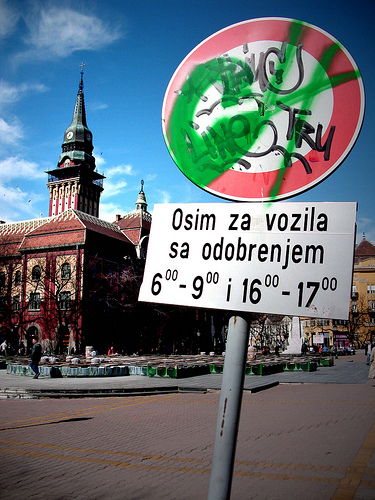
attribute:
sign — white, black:
[137, 200, 359, 322]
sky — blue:
[106, 70, 146, 126]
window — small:
[40, 306, 83, 362]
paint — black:
[279, 105, 331, 147]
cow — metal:
[200, 316, 249, 481]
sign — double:
[140, 18, 364, 321]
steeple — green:
[59, 57, 94, 145]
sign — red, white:
[131, 8, 362, 203]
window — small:
[26, 261, 44, 281]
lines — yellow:
[1, 388, 179, 427]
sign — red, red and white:
[161, 16, 365, 202]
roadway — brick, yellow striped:
[8, 382, 369, 499]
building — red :
[0, 53, 219, 365]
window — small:
[365, 282, 373, 294]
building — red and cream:
[2, 61, 149, 353]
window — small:
[52, 288, 73, 312]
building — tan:
[351, 235, 374, 348]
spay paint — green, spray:
[149, 23, 359, 178]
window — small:
[61, 261, 69, 278]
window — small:
[56, 291, 70, 310]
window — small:
[31, 263, 41, 282]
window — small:
[30, 293, 41, 309]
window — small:
[12, 293, 20, 312]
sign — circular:
[192, 31, 328, 147]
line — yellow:
[24, 394, 152, 443]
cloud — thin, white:
[3, 4, 131, 72]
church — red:
[0, 76, 185, 361]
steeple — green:
[37, 42, 116, 157]